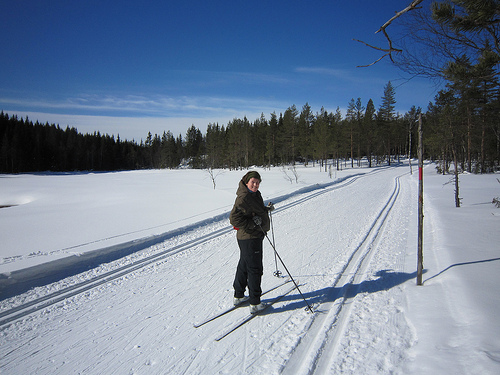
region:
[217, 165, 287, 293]
woman in white snow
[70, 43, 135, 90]
white clouds in blue sky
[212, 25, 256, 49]
white clouds in blue sky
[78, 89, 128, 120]
white clouds in blue sky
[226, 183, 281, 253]
the jacket is brown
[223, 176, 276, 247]
the jacket is brown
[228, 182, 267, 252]
the jacket is brown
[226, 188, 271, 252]
the jacket is brown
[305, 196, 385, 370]
lines on the snow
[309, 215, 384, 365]
lines on the snow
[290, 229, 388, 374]
lines on the snow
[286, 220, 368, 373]
lines on the snow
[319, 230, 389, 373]
lines on the snow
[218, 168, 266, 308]
woman skier in black outfit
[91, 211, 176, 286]
white snow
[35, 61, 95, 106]
white clouds in blue sky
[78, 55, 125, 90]
white clouds in blue sky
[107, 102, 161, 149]
white clouds in blue sky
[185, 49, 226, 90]
white clouds in blue sky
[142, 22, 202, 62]
white clouds in blue sky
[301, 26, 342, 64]
white clouds in blue sky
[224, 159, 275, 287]
skier wearing black outfit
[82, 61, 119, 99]
white clouds in blue sky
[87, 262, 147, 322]
white snow on ground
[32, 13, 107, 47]
white clouds in blue sky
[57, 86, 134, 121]
white clouds in blue sky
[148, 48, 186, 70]
white clouds in blue sky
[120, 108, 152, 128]
white clouds in blue sky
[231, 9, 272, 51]
white clouds in blue sky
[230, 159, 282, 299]
woman skiing in white snow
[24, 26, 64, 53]
white clouds in blue sky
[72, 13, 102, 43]
white clouds in blue sky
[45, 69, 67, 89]
white clouds in blue sky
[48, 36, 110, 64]
white clouds in blue sky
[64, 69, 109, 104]
white clouds in blue sky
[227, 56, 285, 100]
white clouds in blue sky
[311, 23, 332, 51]
white clouds in blue sky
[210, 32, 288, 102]
white clouds in blue sky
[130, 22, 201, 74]
white clouds in blue sky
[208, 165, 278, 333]
woman in black skiing outfit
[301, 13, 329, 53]
white clouds in blue sky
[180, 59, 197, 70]
white clouds in blue sky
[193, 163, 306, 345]
The woman is standing on a set of skis.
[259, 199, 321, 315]
The woman is holding two poles.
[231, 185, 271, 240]
The woman is wearing a jacket.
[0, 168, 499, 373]
Snow is covering the whole ground.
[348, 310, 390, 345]
the snow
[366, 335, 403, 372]
the snow is white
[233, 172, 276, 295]
a women standing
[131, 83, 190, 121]
clouds in the sky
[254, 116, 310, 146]
tall trees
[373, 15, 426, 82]
branches on the tree